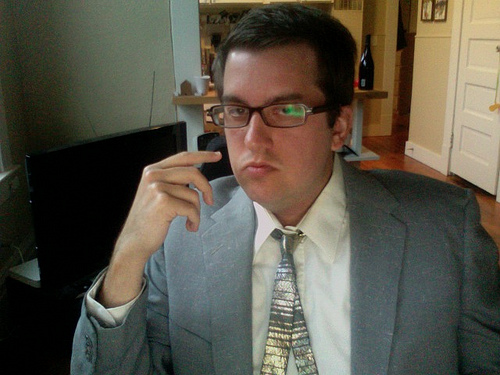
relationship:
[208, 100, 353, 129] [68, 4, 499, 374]
glasses worn by man.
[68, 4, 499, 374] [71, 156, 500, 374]
man wearing suit coat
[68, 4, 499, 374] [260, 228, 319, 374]
man wearing tie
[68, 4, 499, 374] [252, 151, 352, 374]
man wearing shirt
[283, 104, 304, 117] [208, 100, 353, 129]
reflection in glasses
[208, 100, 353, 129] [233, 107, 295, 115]
glasses for eyes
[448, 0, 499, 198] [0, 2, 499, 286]
door in room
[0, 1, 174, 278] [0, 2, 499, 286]
wall in room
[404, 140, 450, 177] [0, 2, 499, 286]
base board in room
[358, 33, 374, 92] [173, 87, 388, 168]
bottle on top of table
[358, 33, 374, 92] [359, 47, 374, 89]
bottle of wine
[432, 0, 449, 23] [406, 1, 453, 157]
picture hanging on wall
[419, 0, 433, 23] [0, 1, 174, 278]
picture hanging on wall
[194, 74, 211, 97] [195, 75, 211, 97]
cup made of foam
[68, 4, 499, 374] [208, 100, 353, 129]
man has glasses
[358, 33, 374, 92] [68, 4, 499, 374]
bottle behind man.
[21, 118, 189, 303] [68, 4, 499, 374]
tv behind man.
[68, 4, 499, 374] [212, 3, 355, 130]
man. has hair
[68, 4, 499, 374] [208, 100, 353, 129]
man. wearing glasses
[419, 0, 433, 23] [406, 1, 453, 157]
picture hanging on wall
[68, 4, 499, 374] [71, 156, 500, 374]
man. wearing suit coat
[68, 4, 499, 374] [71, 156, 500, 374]
man. in suit coat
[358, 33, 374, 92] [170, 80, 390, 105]
bottle on top of counter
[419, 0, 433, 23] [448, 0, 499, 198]
picture hanging by door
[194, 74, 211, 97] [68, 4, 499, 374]
cup behind man.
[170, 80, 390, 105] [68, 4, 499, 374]
counter behind man.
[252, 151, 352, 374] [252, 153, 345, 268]
shirt has a collar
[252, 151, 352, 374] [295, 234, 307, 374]
shirt has buttons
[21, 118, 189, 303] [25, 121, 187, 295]
tv has a screen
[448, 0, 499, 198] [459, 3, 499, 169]
door has panels.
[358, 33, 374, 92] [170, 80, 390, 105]
bottle on a shelf